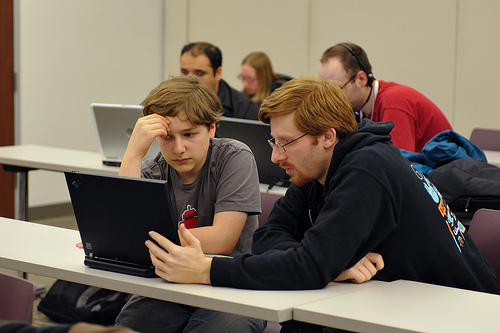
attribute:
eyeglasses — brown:
[261, 126, 316, 151]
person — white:
[260, 68, 497, 307]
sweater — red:
[371, 78, 456, 153]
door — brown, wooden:
[2, 3, 17, 213]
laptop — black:
[65, 164, 217, 275]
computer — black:
[62, 162, 188, 282]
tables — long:
[2, 215, 498, 332]